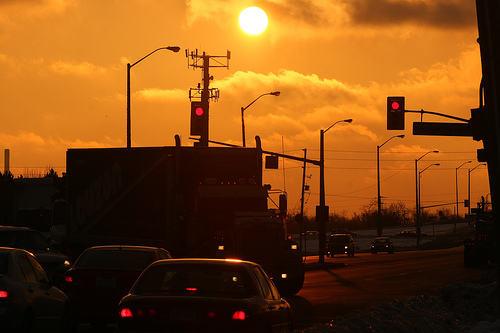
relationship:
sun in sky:
[237, 5, 270, 39] [3, 0, 477, 200]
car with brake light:
[111, 252, 301, 331] [117, 306, 137, 322]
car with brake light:
[111, 252, 301, 331] [226, 309, 246, 324]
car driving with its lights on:
[368, 235, 395, 262] [368, 241, 391, 251]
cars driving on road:
[326, 233, 356, 256] [297, 248, 439, 318]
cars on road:
[4, 212, 387, 327] [324, 248, 467, 305]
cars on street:
[327, 228, 393, 259] [313, 244, 454, 297]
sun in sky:
[237, 5, 270, 39] [3, 4, 469, 112]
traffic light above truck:
[191, 100, 211, 133] [64, 138, 308, 298]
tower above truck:
[183, 46, 233, 149] [64, 138, 308, 298]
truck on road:
[64, 138, 308, 298] [311, 246, 470, 318]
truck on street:
[64, 138, 308, 298] [317, 239, 476, 307]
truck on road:
[64, 138, 308, 298] [323, 246, 480, 301]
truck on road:
[64, 138, 308, 298] [271, 248, 467, 333]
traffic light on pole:
[385, 94, 406, 129] [407, 102, 467, 123]